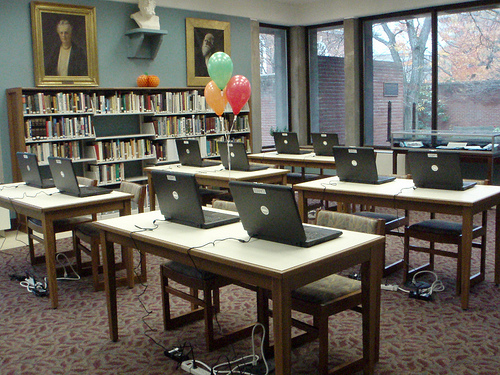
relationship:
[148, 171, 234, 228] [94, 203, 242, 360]
laptop on desk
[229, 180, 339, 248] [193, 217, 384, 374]
laptop on desk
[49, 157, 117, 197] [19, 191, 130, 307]
laptop on desk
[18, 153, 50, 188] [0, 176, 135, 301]
laptop on desk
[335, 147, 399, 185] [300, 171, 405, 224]
laptop on desk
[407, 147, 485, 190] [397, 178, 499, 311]
laptop on desk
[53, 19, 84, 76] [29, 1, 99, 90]
man in portrait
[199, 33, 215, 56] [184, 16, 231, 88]
woman in portrait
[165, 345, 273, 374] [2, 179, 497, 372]
outlet on floor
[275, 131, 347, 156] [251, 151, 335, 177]
laptops on desk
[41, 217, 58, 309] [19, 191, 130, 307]
leg on desk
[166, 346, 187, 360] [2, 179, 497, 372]
port on floor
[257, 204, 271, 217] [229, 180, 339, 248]
logo on laptop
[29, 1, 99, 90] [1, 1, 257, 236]
portrait on wall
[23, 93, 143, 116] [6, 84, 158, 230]
books in shelf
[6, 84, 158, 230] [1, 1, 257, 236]
shelf against wall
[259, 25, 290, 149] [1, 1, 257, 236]
window on wall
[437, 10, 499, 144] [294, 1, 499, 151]
window on wall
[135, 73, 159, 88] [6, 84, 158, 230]
decoration on shelf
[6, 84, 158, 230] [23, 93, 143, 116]
shelf of books